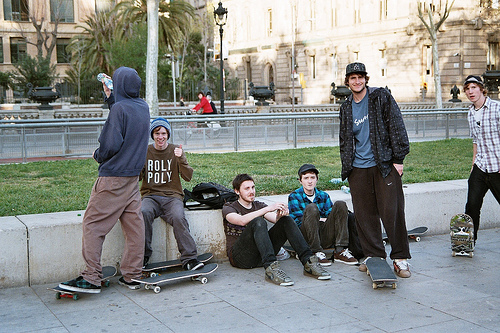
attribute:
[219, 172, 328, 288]
guy — sitting, leaning, lounging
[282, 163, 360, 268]
guy — sitting, leaning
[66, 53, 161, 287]
guy — drinking, lounging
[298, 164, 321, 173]
hat — black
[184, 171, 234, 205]
backpack — black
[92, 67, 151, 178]
sweat shirt — blue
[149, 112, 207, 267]
boy — smiling, sitting, lounging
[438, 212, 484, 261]
skateboard — up, lifted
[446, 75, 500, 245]
boy — lounging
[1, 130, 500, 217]
ground — green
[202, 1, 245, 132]
street lamp — art deco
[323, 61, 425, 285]
boy — smiling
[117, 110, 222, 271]
person — thumbs up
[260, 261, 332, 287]
tennis shoes — white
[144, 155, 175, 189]
roly poly — written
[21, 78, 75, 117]
sculpture — cast iron